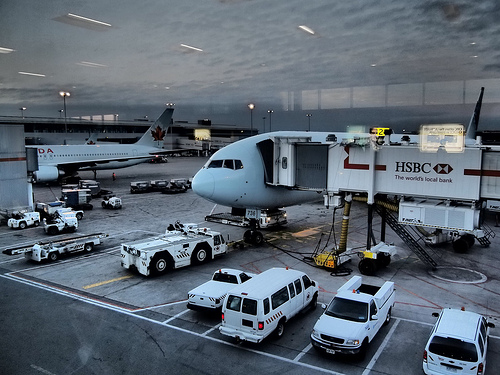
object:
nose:
[191, 170, 214, 198]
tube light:
[181, 44, 204, 51]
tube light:
[299, 26, 315, 34]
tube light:
[68, 13, 111, 26]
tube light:
[18, 72, 45, 77]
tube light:
[0, 47, 12, 54]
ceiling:
[0, 0, 499, 89]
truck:
[187, 269, 257, 309]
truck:
[119, 223, 228, 277]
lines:
[361, 317, 402, 374]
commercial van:
[221, 267, 318, 343]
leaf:
[151, 125, 166, 145]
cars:
[312, 275, 398, 361]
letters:
[395, 162, 405, 172]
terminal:
[328, 143, 500, 199]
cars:
[422, 308, 491, 374]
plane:
[191, 88, 500, 209]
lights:
[248, 104, 255, 110]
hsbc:
[395, 162, 431, 173]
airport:
[0, 124, 499, 374]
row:
[187, 268, 492, 375]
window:
[208, 160, 223, 168]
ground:
[0, 155, 499, 374]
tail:
[135, 108, 174, 145]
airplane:
[26, 108, 174, 183]